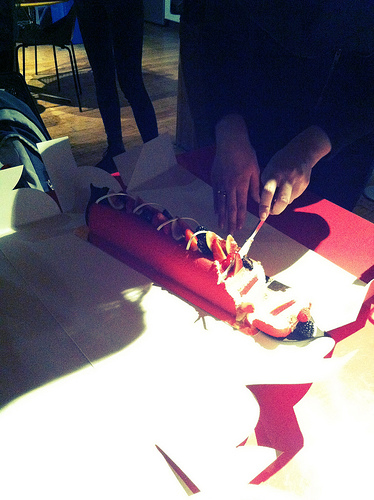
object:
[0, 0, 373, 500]
photo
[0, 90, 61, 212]
backpack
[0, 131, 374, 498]
box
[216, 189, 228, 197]
ring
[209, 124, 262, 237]
hand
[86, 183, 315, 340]
cake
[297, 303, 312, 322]
fruit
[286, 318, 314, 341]
fruit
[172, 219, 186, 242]
fruit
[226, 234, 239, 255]
fruit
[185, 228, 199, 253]
fruit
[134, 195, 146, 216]
fruit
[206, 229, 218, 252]
fruit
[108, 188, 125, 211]
fruit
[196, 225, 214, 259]
fruit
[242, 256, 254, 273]
fruit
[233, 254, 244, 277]
fruit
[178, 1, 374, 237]
person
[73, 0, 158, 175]
person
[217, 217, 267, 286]
knife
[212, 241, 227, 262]
fruit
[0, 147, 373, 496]
table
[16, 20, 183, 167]
floor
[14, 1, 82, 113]
chair